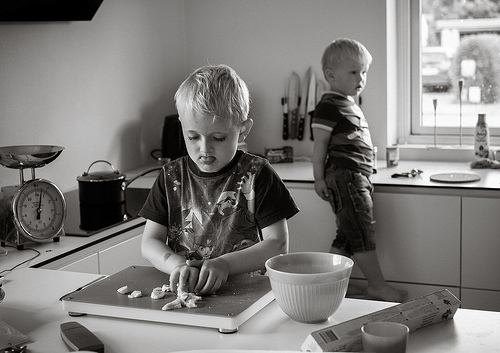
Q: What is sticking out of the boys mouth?
A: Tongue.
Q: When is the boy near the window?
A: Daytime.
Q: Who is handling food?
A: THe older boy.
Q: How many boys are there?
A: Two.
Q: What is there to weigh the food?
A: Scale.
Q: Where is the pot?
A: On the stove.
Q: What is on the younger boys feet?
A: Nothing.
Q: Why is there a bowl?
A: To put food in.